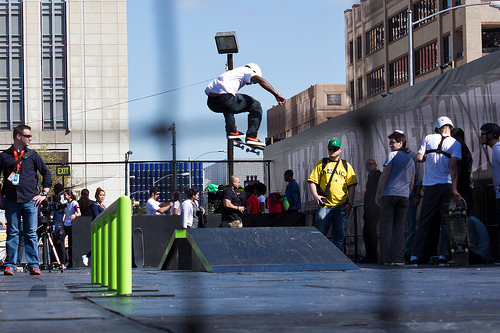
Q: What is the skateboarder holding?
A: A skateboard.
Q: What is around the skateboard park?
A: A fence.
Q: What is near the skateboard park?
A: A concrete building.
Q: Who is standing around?
A: A group of people.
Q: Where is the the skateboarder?
A: In the air.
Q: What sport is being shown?
A: Skateboarding.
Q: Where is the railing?
A: On the left.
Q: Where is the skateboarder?
A: In the air.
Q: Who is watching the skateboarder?
A: A crowd of people.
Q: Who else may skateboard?
A: People in the crowd.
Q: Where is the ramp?
A: Under the skateboard.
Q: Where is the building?
A: Behind the people.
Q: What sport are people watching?
A: Skateboarding.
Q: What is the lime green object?
A: Rail.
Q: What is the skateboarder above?
A: Ramp.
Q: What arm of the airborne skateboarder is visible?
A: Right.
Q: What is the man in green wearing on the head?
A: Hat.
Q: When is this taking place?
A: Daytime.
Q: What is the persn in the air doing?
A: Skateboarding.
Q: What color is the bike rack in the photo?
A: Neon green.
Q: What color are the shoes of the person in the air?
A: Red.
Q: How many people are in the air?
A: One.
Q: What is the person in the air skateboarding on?
A: Ramp.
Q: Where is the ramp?
A: Concrete ground.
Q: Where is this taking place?
A: At a skateboard park.